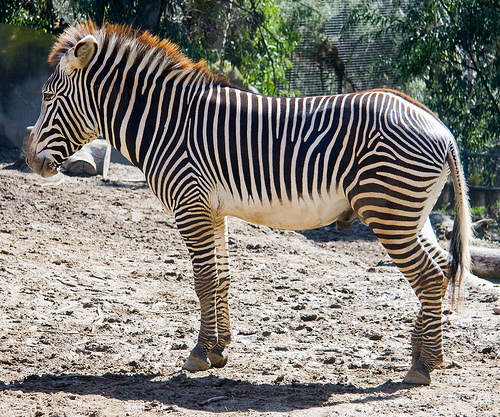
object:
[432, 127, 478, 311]
zebra tail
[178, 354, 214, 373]
hooves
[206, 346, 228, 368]
zebra's feet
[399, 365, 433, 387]
zebra's feet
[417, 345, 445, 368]
zebra's feet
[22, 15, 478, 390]
zebra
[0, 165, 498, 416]
ground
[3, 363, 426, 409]
shadow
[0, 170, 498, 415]
sand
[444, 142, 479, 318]
tail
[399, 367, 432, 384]
hoof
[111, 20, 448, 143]
back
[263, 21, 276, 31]
leaves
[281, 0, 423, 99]
fencing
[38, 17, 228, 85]
mane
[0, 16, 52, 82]
grass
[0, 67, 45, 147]
rock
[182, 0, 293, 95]
tree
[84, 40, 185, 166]
neck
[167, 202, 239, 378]
legs